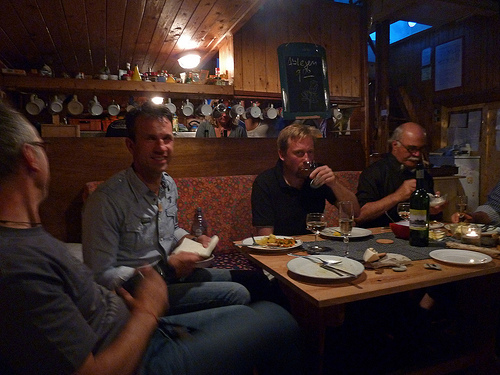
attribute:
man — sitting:
[251, 124, 359, 234]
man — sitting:
[82, 102, 268, 300]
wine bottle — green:
[409, 164, 432, 245]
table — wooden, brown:
[230, 219, 500, 374]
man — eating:
[355, 122, 449, 220]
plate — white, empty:
[287, 254, 363, 279]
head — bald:
[390, 123, 428, 166]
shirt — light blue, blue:
[80, 163, 187, 279]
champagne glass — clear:
[339, 198, 355, 258]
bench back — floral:
[83, 169, 363, 252]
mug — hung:
[197, 96, 212, 119]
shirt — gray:
[2, 221, 139, 370]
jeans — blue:
[154, 264, 263, 312]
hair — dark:
[124, 101, 173, 140]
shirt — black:
[250, 158, 338, 235]